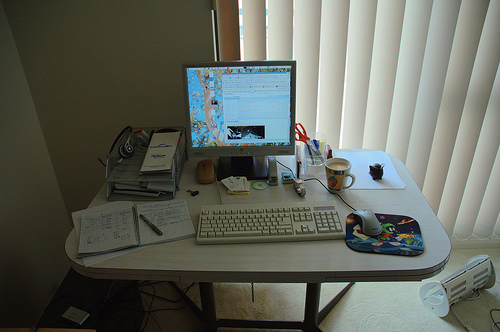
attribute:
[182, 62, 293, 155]
screen — flat, square, on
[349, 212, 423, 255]
pad — blue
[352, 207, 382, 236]
mouse — white, silver, wired, black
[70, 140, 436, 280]
table — square, white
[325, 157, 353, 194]
cup — white, yellow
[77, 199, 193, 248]
notebook — open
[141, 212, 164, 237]
pen — black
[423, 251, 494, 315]
heater — small, white, tipped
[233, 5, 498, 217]
blinds — white, closed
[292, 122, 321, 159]
scissors — orange, red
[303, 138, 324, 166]
cup — clear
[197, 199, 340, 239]
keyboard — white, old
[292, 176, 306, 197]
watch — silver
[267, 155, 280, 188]
stapler — silver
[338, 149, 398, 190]
paper — white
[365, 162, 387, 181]
figurine — paperweight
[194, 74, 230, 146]
tree — background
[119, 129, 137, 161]
headphones — collapsible